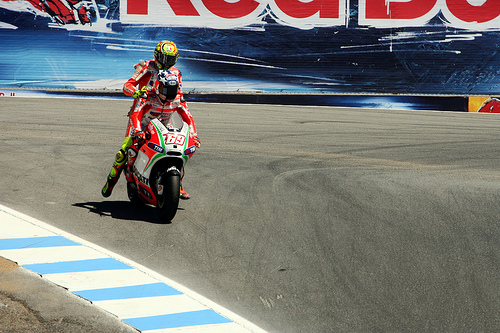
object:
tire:
[155, 167, 181, 221]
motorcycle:
[124, 109, 194, 221]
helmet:
[155, 69, 182, 102]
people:
[125, 70, 202, 200]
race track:
[0, 97, 500, 333]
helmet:
[154, 39, 179, 68]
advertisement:
[0, 0, 499, 115]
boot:
[101, 175, 121, 198]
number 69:
[163, 132, 186, 146]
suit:
[123, 60, 184, 118]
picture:
[0, 0, 500, 333]